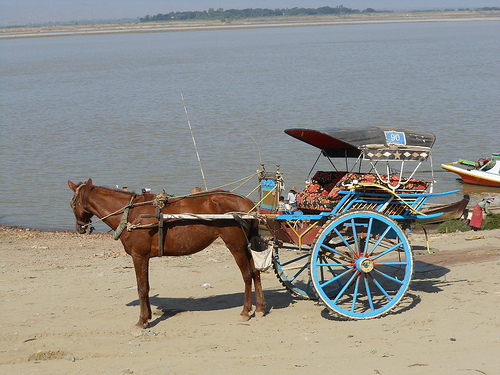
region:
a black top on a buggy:
[281, 117, 450, 168]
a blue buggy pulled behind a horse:
[252, 174, 464, 327]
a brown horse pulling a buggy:
[64, 171, 292, 329]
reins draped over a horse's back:
[125, 161, 277, 211]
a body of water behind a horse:
[1, 20, 497, 209]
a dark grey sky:
[2, 2, 499, 20]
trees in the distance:
[137, 3, 362, 24]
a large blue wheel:
[297, 208, 426, 325]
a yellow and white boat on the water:
[441, 147, 498, 188]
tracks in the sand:
[2, 322, 207, 342]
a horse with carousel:
[80, 111, 470, 370]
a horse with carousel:
[152, 159, 417, 327]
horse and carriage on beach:
[67, 153, 463, 347]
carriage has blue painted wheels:
[256, 152, 457, 350]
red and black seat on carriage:
[299, 159, 431, 249]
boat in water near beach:
[444, 139, 496, 252]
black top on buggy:
[286, 114, 455, 256]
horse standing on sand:
[54, 165, 271, 343]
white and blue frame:
[159, 176, 458, 238]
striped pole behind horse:
[152, 77, 239, 211]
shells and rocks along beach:
[7, 199, 149, 272]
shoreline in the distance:
[114, 7, 459, 50]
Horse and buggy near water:
[58, 134, 433, 339]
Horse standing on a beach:
[57, 167, 295, 325]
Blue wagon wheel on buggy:
[294, 187, 425, 338]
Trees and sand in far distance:
[123, 12, 313, 33]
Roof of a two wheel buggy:
[275, 95, 438, 185]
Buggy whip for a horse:
[145, 92, 245, 208]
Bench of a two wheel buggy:
[276, 156, 396, 228]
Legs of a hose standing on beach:
[121, 233, 272, 314]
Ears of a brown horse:
[63, 170, 103, 200]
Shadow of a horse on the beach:
[117, 276, 298, 330]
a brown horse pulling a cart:
[50, 176, 277, 324]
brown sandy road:
[12, 292, 85, 372]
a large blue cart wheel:
[299, 212, 413, 312]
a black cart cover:
[283, 121, 437, 166]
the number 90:
[391, 133, 405, 145]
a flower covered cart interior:
[298, 173, 410, 214]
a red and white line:
[173, 97, 226, 194]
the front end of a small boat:
[442, 151, 499, 203]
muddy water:
[26, 105, 148, 180]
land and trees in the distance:
[10, 0, 497, 31]